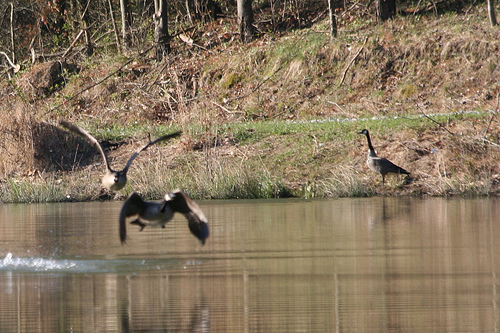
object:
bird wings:
[119, 192, 149, 247]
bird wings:
[168, 187, 210, 247]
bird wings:
[124, 131, 182, 174]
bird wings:
[57, 116, 112, 173]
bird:
[119, 187, 210, 248]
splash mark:
[0, 251, 76, 271]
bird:
[58, 118, 184, 193]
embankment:
[0, 0, 500, 203]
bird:
[357, 129, 411, 186]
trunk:
[326, 0, 338, 35]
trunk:
[119, 0, 131, 48]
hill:
[0, 0, 500, 186]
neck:
[366, 135, 376, 153]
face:
[358, 129, 368, 134]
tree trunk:
[152, 0, 171, 61]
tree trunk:
[235, 0, 254, 44]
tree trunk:
[373, 0, 390, 23]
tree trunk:
[485, 0, 498, 27]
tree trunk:
[84, 30, 93, 57]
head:
[357, 129, 369, 135]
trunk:
[236, 1, 260, 42]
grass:
[0, 1, 500, 205]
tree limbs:
[211, 34, 371, 119]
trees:
[0, 0, 500, 71]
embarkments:
[0, 195, 500, 333]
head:
[113, 171, 120, 181]